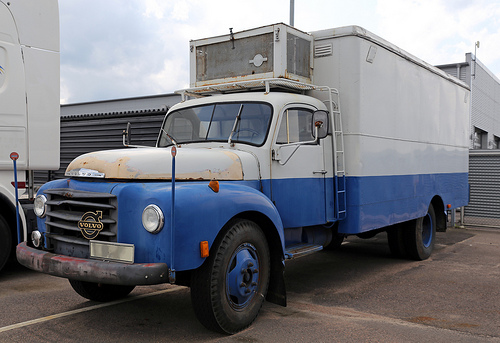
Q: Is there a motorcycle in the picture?
A: No, there are no motorcycles.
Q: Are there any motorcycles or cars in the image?
A: No, there are no motorcycles or cars.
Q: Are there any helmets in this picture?
A: No, there are no helmets.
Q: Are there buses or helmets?
A: No, there are no helmets or buses.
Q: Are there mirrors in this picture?
A: Yes, there is a mirror.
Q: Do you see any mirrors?
A: Yes, there is a mirror.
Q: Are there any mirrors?
A: Yes, there is a mirror.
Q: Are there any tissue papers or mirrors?
A: Yes, there is a mirror.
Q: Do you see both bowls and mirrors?
A: No, there is a mirror but no bowls.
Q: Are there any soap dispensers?
A: No, there are no soap dispensers.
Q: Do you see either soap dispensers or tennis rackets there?
A: No, there are no soap dispensers or tennis rackets.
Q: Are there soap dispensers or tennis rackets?
A: No, there are no soap dispensers or tennis rackets.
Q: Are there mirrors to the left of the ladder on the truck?
A: Yes, there is a mirror to the left of the ladder.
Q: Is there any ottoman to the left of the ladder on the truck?
A: No, there is a mirror to the left of the ladder.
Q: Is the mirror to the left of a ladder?
A: Yes, the mirror is to the left of a ladder.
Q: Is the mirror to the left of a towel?
A: No, the mirror is to the left of a ladder.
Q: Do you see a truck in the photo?
A: Yes, there is a truck.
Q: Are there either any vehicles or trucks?
A: Yes, there is a truck.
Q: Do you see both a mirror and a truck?
A: Yes, there are both a truck and a mirror.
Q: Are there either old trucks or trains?
A: Yes, there is an old truck.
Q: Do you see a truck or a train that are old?
A: Yes, the truck is old.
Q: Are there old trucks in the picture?
A: Yes, there is an old truck.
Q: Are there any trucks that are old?
A: Yes, there is a truck that is old.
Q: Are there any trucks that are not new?
A: Yes, there is a old truck.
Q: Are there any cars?
A: No, there are no cars.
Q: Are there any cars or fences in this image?
A: No, there are no cars or fences.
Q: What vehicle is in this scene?
A: The vehicle is a truck.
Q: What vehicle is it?
A: The vehicle is a truck.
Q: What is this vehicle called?
A: This is a truck.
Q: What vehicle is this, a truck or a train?
A: This is a truck.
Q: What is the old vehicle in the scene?
A: The vehicle is a truck.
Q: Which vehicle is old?
A: The vehicle is a truck.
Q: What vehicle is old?
A: The vehicle is a truck.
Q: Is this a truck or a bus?
A: This is a truck.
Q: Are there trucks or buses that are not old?
A: No, there is a truck but it is old.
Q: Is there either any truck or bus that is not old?
A: No, there is a truck but it is old.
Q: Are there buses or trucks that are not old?
A: No, there is a truck but it is old.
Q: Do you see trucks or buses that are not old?
A: No, there is a truck but it is old.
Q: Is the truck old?
A: Yes, the truck is old.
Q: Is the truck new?
A: No, the truck is old.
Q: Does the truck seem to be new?
A: No, the truck is old.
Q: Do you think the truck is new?
A: No, the truck is old.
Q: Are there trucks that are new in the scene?
A: No, there is a truck but it is old.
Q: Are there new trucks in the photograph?
A: No, there is a truck but it is old.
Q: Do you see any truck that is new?
A: No, there is a truck but it is old.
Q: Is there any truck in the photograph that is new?
A: No, there is a truck but it is old.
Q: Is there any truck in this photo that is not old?
A: No, there is a truck but it is old.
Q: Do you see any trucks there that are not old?
A: No, there is a truck but it is old.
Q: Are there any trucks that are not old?
A: No, there is a truck but it is old.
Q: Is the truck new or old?
A: The truck is old.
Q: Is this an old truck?
A: Yes, this is an old truck.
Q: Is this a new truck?
A: No, this is an old truck.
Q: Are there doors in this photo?
A: Yes, there is a door.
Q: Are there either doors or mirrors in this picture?
A: Yes, there is a door.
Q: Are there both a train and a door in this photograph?
A: No, there is a door but no trains.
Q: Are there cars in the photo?
A: No, there are no cars.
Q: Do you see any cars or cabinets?
A: No, there are no cars or cabinets.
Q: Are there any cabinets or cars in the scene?
A: No, there are no cars or cabinets.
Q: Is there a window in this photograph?
A: Yes, there are windows.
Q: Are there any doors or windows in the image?
A: Yes, there are windows.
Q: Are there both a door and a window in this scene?
A: Yes, there are both a window and a door.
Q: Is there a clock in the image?
A: No, there are no clocks.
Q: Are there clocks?
A: No, there are no clocks.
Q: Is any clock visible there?
A: No, there are no clocks.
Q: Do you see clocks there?
A: No, there are no clocks.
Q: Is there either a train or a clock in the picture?
A: No, there are no clocks or trains.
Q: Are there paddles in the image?
A: No, there are no paddles.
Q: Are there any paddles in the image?
A: No, there are no paddles.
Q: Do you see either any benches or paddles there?
A: No, there are no paddles or benches.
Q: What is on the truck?
A: The ladder is on the truck.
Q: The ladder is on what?
A: The ladder is on the truck.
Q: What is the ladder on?
A: The ladder is on the truck.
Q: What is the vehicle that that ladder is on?
A: The vehicle is a truck.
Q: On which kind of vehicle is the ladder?
A: The ladder is on the truck.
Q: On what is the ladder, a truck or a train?
A: The ladder is on a truck.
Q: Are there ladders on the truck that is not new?
A: Yes, there is a ladder on the truck.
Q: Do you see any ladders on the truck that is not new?
A: Yes, there is a ladder on the truck.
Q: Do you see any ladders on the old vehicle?
A: Yes, there is a ladder on the truck.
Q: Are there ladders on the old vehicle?
A: Yes, there is a ladder on the truck.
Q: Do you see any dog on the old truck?
A: No, there is a ladder on the truck.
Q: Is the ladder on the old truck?
A: Yes, the ladder is on the truck.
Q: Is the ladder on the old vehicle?
A: Yes, the ladder is on the truck.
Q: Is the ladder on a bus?
A: No, the ladder is on the truck.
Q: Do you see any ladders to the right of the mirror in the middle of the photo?
A: Yes, there is a ladder to the right of the mirror.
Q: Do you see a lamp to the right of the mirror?
A: No, there is a ladder to the right of the mirror.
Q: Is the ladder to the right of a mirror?
A: Yes, the ladder is to the right of a mirror.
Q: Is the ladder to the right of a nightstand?
A: No, the ladder is to the right of a mirror.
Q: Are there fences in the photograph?
A: No, there are no fences.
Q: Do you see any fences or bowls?
A: No, there are no fences or bowls.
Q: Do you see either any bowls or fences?
A: No, there are no fences or bowls.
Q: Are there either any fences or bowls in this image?
A: No, there are no fences or bowls.